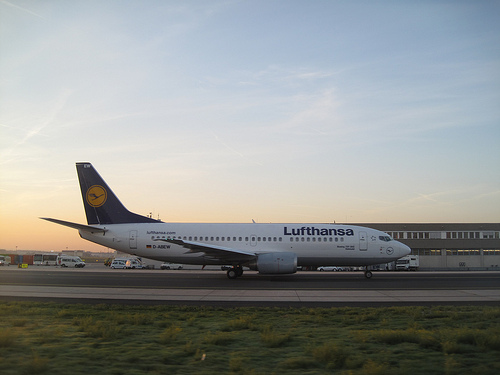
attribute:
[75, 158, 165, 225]
tail — blue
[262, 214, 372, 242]
letters — blue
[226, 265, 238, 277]
wheel — back, black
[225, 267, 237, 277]
landing gear — rear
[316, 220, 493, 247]
roof — brown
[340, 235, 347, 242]
window — a passenger window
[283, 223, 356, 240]
writing — blue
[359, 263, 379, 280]
wheel — black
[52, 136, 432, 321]
plane — round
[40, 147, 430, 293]
plane — blue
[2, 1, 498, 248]
sky — behind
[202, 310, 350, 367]
grass —  green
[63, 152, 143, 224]
tail — blue, yellow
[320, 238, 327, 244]
window —   a passenger window 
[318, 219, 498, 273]
building — behind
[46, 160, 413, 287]
plane — white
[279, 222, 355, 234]
lufthansa — painted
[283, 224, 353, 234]
logo — corprate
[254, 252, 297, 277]
engine — white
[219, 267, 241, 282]
wheel — round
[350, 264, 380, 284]
gear — landing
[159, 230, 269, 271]
wing — silver